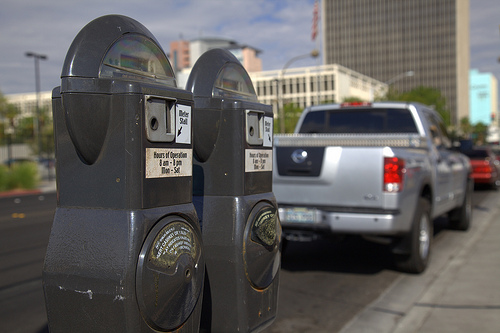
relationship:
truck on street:
[276, 93, 481, 276] [287, 245, 470, 320]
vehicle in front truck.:
[462, 141, 499, 188] [276, 93, 481, 276]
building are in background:
[321, 0, 470, 128] [6, 4, 499, 56]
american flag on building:
[310, 3, 321, 43] [258, 3, 379, 104]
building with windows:
[321, 0, 477, 122] [331, 5, 454, 73]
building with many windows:
[321, 0, 477, 122] [331, 5, 454, 73]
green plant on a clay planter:
[0, 158, 40, 187] [1, 188, 43, 199]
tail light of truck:
[379, 154, 408, 195] [276, 93, 481, 276]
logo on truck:
[360, 191, 384, 208] [276, 93, 481, 276]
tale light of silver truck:
[379, 154, 408, 195] [276, 93, 481, 276]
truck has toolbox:
[276, 93, 481, 276] [273, 132, 430, 152]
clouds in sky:
[8, 3, 308, 30] [0, 0, 499, 95]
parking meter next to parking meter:
[185, 47, 279, 331] [44, 13, 207, 331]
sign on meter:
[143, 145, 193, 177] [140, 145, 195, 183]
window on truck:
[294, 105, 422, 136] [271, 102, 472, 273]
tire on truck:
[389, 195, 439, 281] [271, 102, 472, 273]